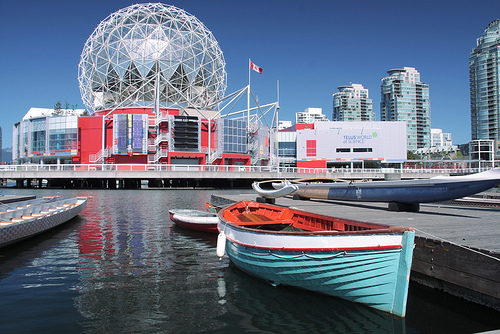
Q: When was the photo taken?
A: Daytime.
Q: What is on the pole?
A: A flag.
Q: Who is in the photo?
A: Nobody.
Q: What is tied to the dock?
A: A boat.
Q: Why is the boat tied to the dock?
A: So it doesn't float away.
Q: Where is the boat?
A: In the water.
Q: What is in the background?
A: Buildings.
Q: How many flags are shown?
A: One.